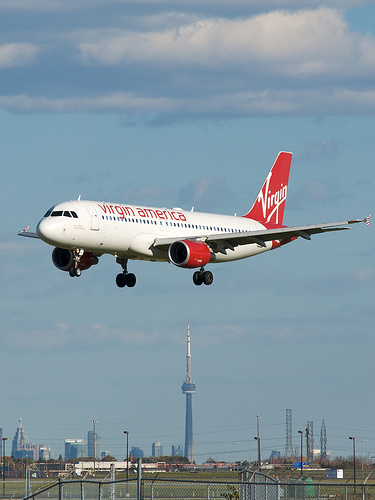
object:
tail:
[239, 152, 292, 225]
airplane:
[18, 151, 373, 287]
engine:
[168, 241, 212, 269]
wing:
[155, 212, 371, 255]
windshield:
[44, 208, 77, 220]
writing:
[96, 201, 188, 223]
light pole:
[346, 434, 356, 498]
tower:
[182, 323, 197, 458]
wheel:
[116, 271, 136, 288]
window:
[100, 215, 106, 222]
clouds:
[0, 6, 374, 118]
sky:
[0, 0, 374, 468]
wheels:
[69, 266, 217, 290]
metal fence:
[0, 481, 375, 500]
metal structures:
[283, 408, 328, 470]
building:
[11, 417, 42, 460]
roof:
[13, 415, 27, 433]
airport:
[0, 438, 374, 465]